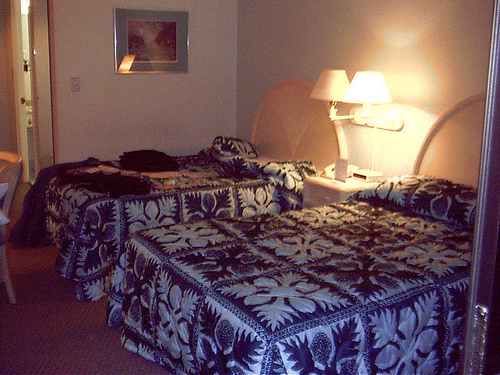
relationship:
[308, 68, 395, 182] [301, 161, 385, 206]
lamps above table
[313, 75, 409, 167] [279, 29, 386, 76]
lamps on wall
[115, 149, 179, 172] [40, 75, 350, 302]
bag on bed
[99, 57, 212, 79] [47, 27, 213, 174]
picture on wall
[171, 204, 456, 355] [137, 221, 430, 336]
bed has covers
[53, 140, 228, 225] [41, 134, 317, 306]
bed has covers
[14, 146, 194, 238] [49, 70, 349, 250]
clothes on bed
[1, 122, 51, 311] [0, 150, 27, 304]
seat of a seat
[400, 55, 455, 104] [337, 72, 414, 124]
wall mounted lights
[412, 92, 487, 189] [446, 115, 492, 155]
head board blonde wood